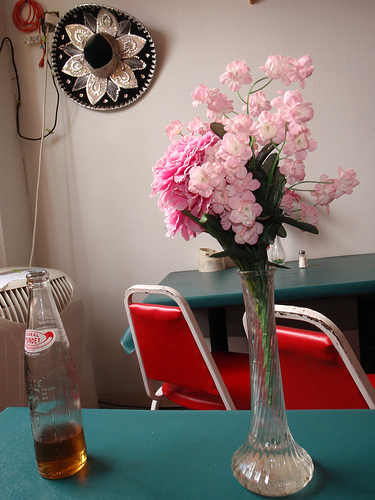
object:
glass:
[272, 258, 285, 264]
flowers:
[148, 54, 360, 270]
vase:
[231, 267, 315, 497]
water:
[230, 428, 314, 497]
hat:
[51, 3, 157, 112]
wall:
[318, 1, 375, 69]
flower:
[57, 8, 147, 106]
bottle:
[23, 269, 86, 480]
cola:
[34, 422, 89, 479]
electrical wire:
[0, 0, 59, 141]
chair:
[122, 283, 250, 411]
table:
[120, 253, 374, 375]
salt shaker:
[298, 250, 307, 269]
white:
[77, 157, 130, 233]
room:
[0, 0, 375, 500]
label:
[24, 330, 56, 353]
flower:
[220, 60, 253, 93]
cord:
[12, 0, 45, 68]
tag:
[23, 34, 42, 46]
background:
[0, 0, 374, 318]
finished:
[27, 364, 80, 432]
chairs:
[241, 303, 374, 410]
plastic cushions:
[151, 315, 189, 368]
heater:
[0, 266, 98, 408]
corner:
[1, 2, 13, 407]